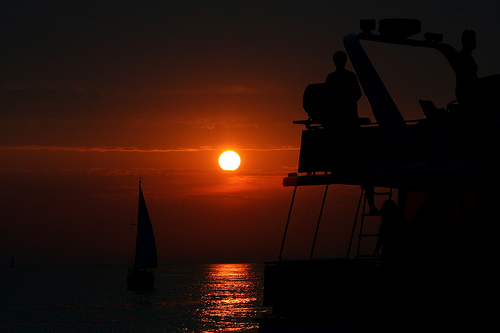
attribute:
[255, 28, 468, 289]
boat — large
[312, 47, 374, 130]
person — silhouette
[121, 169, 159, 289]
sail boat — small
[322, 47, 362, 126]
figure — shadowy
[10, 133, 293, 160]
line sky — white, wavy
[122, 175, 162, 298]
sail — dark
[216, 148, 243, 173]
bright sun — orange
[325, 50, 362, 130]
silhouette — a man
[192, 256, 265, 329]
seawater — beautiful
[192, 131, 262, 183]
sun — spooky